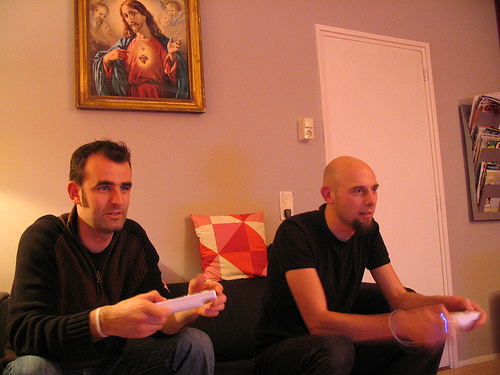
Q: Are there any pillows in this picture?
A: Yes, there is a pillow.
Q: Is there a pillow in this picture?
A: Yes, there is a pillow.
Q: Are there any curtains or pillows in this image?
A: Yes, there is a pillow.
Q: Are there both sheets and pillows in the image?
A: No, there is a pillow but no sheets.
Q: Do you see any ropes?
A: No, there are no ropes.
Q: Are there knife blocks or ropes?
A: No, there are no ropes or knife blocks.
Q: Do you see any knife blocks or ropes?
A: No, there are no ropes or knife blocks.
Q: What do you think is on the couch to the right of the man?
A: The pillow is on the couch.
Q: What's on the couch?
A: The pillow is on the couch.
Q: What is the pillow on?
A: The pillow is on the couch.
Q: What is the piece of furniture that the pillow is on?
A: The piece of furniture is a couch.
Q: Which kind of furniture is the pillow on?
A: The pillow is on the couch.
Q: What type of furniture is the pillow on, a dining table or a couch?
A: The pillow is on a couch.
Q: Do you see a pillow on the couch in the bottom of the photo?
A: Yes, there is a pillow on the couch.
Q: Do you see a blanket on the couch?
A: No, there is a pillow on the couch.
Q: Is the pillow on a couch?
A: Yes, the pillow is on a couch.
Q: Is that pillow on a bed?
A: No, the pillow is on a couch.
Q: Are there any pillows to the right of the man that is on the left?
A: Yes, there is a pillow to the right of the man.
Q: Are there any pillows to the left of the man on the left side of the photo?
A: No, the pillow is to the right of the man.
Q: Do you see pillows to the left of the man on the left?
A: No, the pillow is to the right of the man.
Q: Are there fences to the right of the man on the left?
A: No, there is a pillow to the right of the man.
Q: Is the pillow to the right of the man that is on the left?
A: Yes, the pillow is to the right of the man.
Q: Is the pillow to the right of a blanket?
A: No, the pillow is to the right of the man.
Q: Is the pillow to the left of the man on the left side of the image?
A: No, the pillow is to the right of the man.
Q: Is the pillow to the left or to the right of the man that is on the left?
A: The pillow is to the right of the man.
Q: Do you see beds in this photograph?
A: No, there are no beds.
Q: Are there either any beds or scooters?
A: No, there are no beds or scooters.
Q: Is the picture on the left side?
A: Yes, the picture is on the left of the image.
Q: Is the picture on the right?
A: No, the picture is on the left of the image.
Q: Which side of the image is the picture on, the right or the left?
A: The picture is on the left of the image.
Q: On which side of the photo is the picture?
A: The picture is on the left of the image.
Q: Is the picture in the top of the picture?
A: Yes, the picture is in the top of the image.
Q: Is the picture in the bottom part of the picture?
A: No, the picture is in the top of the image.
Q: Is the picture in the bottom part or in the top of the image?
A: The picture is in the top of the image.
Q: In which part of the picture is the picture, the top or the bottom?
A: The picture is in the top of the image.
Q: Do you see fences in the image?
A: No, there are no fences.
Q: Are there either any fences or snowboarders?
A: No, there are no fences or snowboarders.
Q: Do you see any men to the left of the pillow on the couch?
A: Yes, there is a man to the left of the pillow.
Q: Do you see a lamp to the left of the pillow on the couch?
A: No, there is a man to the left of the pillow.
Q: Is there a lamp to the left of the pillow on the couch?
A: No, there is a man to the left of the pillow.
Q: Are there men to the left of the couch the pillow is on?
A: Yes, there is a man to the left of the couch.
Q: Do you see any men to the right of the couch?
A: No, the man is to the left of the couch.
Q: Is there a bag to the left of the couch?
A: No, there is a man to the left of the couch.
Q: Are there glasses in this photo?
A: No, there are no glasses.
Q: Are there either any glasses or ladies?
A: No, there are no glasses or ladies.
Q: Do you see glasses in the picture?
A: No, there are no glasses.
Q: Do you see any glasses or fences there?
A: No, there are no glasses or fences.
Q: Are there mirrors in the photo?
A: No, there are no mirrors.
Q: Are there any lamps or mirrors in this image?
A: No, there are no mirrors or lamps.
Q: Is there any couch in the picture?
A: Yes, there is a couch.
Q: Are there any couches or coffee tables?
A: Yes, there is a couch.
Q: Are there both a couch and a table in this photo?
A: No, there is a couch but no tables.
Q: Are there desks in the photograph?
A: No, there are no desks.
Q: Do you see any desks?
A: No, there are no desks.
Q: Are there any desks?
A: No, there are no desks.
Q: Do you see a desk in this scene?
A: No, there are no desks.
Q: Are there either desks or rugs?
A: No, there are no desks or rugs.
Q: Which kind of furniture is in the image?
A: The furniture is a couch.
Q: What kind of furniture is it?
A: The piece of furniture is a couch.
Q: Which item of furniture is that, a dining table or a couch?
A: This is a couch.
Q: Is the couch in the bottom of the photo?
A: Yes, the couch is in the bottom of the image.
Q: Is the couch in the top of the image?
A: No, the couch is in the bottom of the image.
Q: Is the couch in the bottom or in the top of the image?
A: The couch is in the bottom of the image.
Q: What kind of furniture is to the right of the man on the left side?
A: The piece of furniture is a couch.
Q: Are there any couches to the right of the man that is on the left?
A: Yes, there is a couch to the right of the man.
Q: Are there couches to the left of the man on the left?
A: No, the couch is to the right of the man.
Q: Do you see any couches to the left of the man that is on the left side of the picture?
A: No, the couch is to the right of the man.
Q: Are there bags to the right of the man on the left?
A: No, there is a couch to the right of the man.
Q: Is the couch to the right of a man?
A: Yes, the couch is to the right of a man.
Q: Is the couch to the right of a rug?
A: No, the couch is to the right of a man.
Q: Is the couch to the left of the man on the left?
A: No, the couch is to the right of the man.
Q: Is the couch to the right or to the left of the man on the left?
A: The couch is to the right of the man.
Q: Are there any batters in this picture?
A: No, there are no batters.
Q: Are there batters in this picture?
A: No, there are no batters.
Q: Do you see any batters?
A: No, there are no batters.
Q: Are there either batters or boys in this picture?
A: No, there are no batters or boys.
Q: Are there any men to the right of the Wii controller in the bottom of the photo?
A: Yes, there is a man to the right of the Wii remotes.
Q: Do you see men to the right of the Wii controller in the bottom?
A: Yes, there is a man to the right of the Wii remotes.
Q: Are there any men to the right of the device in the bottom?
A: Yes, there is a man to the right of the Wii remotes.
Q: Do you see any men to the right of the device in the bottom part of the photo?
A: Yes, there is a man to the right of the Wii remotes.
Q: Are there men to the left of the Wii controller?
A: No, the man is to the right of the Wii controller.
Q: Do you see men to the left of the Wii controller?
A: No, the man is to the right of the Wii controller.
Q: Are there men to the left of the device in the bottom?
A: No, the man is to the right of the Wii controller.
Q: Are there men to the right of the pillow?
A: Yes, there is a man to the right of the pillow.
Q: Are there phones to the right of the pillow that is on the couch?
A: No, there is a man to the right of the pillow.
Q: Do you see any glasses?
A: No, there are no glasses.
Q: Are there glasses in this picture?
A: No, there are no glasses.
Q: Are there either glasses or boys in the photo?
A: No, there are no glasses or boys.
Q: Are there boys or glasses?
A: No, there are no glasses or boys.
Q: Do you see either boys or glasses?
A: No, there are no glasses or boys.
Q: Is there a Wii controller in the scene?
A: Yes, there is a Wii controller.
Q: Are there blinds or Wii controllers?
A: Yes, there is a Wii controller.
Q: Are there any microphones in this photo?
A: No, there are no microphones.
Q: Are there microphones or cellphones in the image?
A: No, there are no microphones or cellphones.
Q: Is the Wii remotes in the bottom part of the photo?
A: Yes, the Wii remotes is in the bottom of the image.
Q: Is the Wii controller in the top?
A: No, the Wii controller is in the bottom of the image.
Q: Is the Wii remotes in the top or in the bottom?
A: The Wii remotes is in the bottom of the image.